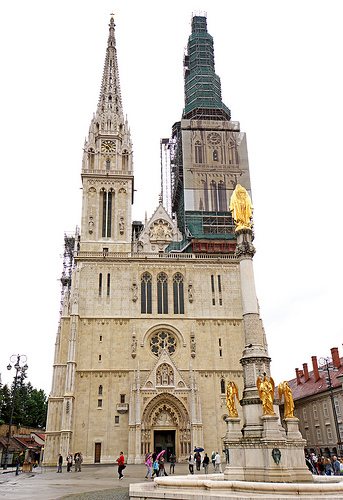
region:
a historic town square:
[3, 14, 341, 494]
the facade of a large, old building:
[40, 1, 290, 468]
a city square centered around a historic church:
[0, 3, 340, 496]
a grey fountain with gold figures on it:
[215, 182, 316, 490]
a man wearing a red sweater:
[113, 450, 128, 480]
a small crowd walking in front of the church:
[50, 445, 221, 484]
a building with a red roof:
[292, 344, 340, 448]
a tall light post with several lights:
[1, 349, 28, 478]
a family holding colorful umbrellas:
[138, 444, 169, 482]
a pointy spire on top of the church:
[88, 5, 128, 129]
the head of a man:
[117, 448, 125, 456]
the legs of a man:
[114, 463, 124, 477]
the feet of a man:
[115, 472, 125, 481]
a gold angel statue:
[220, 376, 243, 417]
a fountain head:
[269, 446, 284, 466]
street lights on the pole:
[3, 359, 35, 377]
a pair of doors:
[150, 426, 178, 459]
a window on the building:
[134, 269, 154, 316]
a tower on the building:
[73, 9, 137, 249]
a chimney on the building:
[308, 354, 321, 380]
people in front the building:
[65, 452, 204, 468]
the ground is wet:
[12, 475, 57, 492]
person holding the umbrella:
[185, 434, 206, 471]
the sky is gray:
[279, 65, 309, 151]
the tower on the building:
[81, 10, 141, 247]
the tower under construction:
[161, 9, 256, 243]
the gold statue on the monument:
[225, 179, 262, 234]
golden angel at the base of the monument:
[211, 376, 243, 416]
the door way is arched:
[136, 391, 189, 458]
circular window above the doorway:
[141, 324, 183, 358]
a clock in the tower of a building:
[99, 137, 120, 156]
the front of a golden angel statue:
[253, 370, 276, 414]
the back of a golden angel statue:
[275, 375, 293, 413]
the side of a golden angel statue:
[222, 377, 241, 416]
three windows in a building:
[138, 268, 186, 317]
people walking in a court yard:
[146, 441, 224, 478]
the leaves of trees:
[24, 391, 42, 417]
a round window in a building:
[141, 322, 190, 358]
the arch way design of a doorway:
[140, 396, 197, 463]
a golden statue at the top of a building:
[227, 179, 256, 232]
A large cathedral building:
[30, 1, 284, 462]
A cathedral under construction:
[22, 2, 340, 475]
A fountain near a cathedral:
[146, 175, 339, 497]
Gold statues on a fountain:
[196, 366, 309, 422]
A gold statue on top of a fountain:
[226, 178, 256, 239]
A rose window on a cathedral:
[141, 322, 192, 369]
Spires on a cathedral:
[83, 5, 139, 185]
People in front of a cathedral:
[34, 437, 257, 497]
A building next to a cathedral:
[262, 360, 341, 457]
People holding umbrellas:
[129, 437, 219, 480]